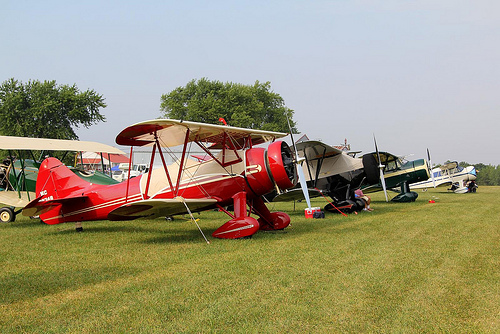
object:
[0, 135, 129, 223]
airplane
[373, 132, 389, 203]
propeller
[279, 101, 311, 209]
propeller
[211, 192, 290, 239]
landing gear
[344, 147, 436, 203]
airplane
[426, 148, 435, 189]
propellor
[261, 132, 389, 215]
planes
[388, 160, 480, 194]
airplane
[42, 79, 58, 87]
top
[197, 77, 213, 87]
top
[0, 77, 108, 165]
tree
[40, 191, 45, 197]
writing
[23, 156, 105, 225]
tail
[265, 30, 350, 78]
blue sky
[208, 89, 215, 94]
leaves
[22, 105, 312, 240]
plane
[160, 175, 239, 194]
stripes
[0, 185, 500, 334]
grass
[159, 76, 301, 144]
tree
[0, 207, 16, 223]
back wheel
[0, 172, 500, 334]
ground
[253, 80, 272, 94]
top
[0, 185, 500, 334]
field